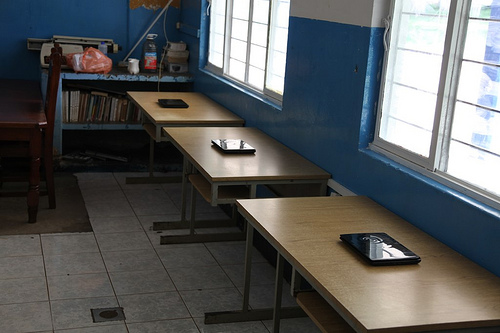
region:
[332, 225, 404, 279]
laptop on a table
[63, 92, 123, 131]
books on a shelf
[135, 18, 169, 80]
juice on the shelf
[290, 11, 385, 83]
Blue and white wall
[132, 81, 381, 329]
Laptops on a table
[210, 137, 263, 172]
Black laptop on a table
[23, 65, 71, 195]
Chair in front of a table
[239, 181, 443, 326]
Wood desk with laptop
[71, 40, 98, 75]
plastic bag on a shelf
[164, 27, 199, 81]
Books on top of a table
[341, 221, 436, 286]
THIS IPAD IS NOT TURNED ON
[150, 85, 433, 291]
THESE ARE THREE IPADS IN THE MIDDLE OF THE DESKS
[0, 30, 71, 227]
THIS IS A TABLE AND CHAIR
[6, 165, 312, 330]
THE FLOOR IS COVERED IN TILES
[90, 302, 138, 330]
THIS IS A DRAIN ON THE FLOOR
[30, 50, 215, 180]
THIS BOOKSHELF HAS MANY BOOKS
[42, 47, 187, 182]
THIS IS A BLUE BOOKSHELF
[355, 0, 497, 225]
THIS IS A BIG WINDOW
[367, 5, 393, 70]
THIS IS A WINDOW LATCH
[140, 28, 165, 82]
THIS IS A BOTTLE OF JUICE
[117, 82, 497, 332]
the tables are brown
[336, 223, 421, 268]
the laptop is black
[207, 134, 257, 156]
the laptop is shiny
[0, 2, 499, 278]
the walls are black and white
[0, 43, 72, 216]
the chair is brown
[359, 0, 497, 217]
the window is big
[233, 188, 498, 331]
the laptop is on the table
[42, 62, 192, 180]
a bookshelf with books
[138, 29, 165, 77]
a plastic bottle on the book shelf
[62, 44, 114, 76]
a bag on the book shelf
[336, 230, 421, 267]
Black laptop on table.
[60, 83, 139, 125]
Books on shelf in the background.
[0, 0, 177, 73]
Blue wall in the background.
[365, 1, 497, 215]
Windows in the wall.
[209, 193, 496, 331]
Light brown table in the front.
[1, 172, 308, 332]
Tan tile on the floor.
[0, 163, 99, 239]
Brown rug on the floor.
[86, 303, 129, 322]
Drain in the floor.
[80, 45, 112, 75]
Bag on the bookshelf.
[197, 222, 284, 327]
Gray metal table leg.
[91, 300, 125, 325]
small drain in tile floor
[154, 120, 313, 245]
wooden desk against the wall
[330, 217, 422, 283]
small laptop on top of desk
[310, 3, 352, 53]
blue and white painted wall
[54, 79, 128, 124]
line of books on a shelf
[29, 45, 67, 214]
brown wooden chair at a table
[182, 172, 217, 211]
keyboard tray under the desk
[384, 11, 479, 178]
double window in the wall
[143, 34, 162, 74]
bottle of juice on the shelf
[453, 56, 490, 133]
bars outside the window